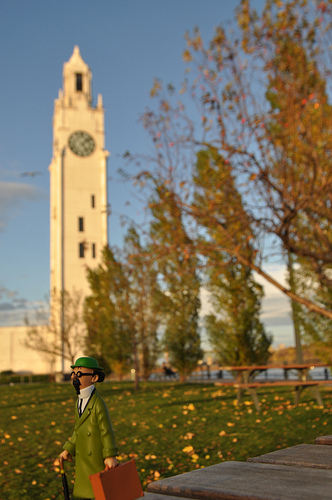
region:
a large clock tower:
[31, 32, 149, 211]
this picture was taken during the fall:
[13, 300, 330, 486]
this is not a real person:
[36, 354, 152, 491]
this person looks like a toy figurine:
[46, 348, 250, 497]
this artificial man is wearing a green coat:
[4, 340, 155, 496]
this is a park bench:
[202, 343, 331, 435]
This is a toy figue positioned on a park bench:
[5, 323, 326, 492]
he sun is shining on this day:
[10, 103, 272, 336]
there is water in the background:
[115, 311, 328, 410]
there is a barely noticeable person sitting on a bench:
[135, 349, 192, 393]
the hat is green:
[57, 345, 108, 372]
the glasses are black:
[67, 368, 94, 379]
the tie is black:
[72, 396, 87, 418]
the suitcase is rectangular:
[91, 460, 162, 497]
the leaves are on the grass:
[162, 411, 216, 461]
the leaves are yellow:
[156, 390, 209, 454]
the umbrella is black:
[46, 456, 72, 493]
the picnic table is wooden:
[201, 336, 328, 420]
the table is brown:
[206, 350, 322, 412]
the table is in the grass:
[210, 347, 328, 417]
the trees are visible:
[93, 170, 291, 383]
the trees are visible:
[150, 244, 261, 482]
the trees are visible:
[110, 170, 212, 367]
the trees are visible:
[160, 193, 198, 394]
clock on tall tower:
[63, 129, 98, 163]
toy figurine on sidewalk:
[52, 355, 130, 494]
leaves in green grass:
[186, 448, 203, 463]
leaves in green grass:
[213, 426, 224, 435]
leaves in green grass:
[251, 415, 261, 424]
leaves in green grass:
[179, 430, 190, 438]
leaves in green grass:
[170, 421, 179, 427]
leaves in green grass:
[134, 436, 148, 442]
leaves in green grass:
[27, 475, 40, 483]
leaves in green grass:
[130, 415, 151, 428]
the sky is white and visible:
[70, 31, 230, 165]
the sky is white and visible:
[14, 6, 303, 232]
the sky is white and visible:
[15, 0, 176, 140]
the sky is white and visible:
[23, 59, 168, 191]